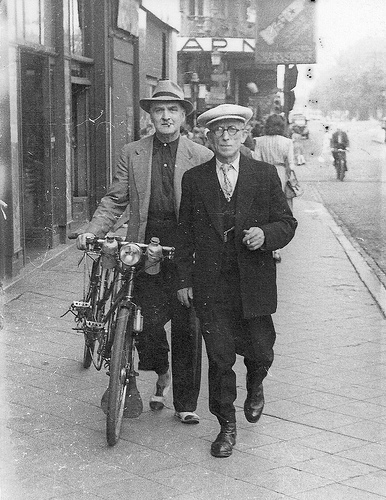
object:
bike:
[56, 225, 184, 448]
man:
[86, 108, 191, 433]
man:
[193, 119, 311, 463]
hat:
[137, 76, 195, 110]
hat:
[194, 103, 266, 131]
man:
[173, 102, 293, 452]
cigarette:
[244, 233, 258, 250]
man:
[176, 108, 333, 391]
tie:
[209, 148, 281, 205]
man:
[329, 125, 349, 174]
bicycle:
[331, 147, 349, 179]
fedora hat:
[135, 78, 201, 115]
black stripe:
[148, 89, 182, 98]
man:
[76, 65, 224, 427]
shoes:
[176, 409, 201, 424]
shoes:
[150, 374, 171, 410]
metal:
[146, 240, 164, 281]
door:
[15, 46, 53, 265]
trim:
[15, 42, 57, 264]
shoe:
[171, 402, 199, 425]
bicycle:
[69, 229, 185, 445]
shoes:
[143, 369, 166, 410]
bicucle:
[52, 222, 167, 437]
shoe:
[212, 422, 242, 457]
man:
[135, 78, 200, 165]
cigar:
[166, 121, 170, 131]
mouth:
[162, 120, 170, 129]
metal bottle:
[141, 236, 167, 277]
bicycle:
[58, 228, 178, 449]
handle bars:
[66, 227, 174, 274]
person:
[176, 90, 319, 472]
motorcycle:
[328, 148, 350, 184]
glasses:
[198, 120, 254, 143]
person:
[327, 123, 350, 186]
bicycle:
[329, 148, 350, 186]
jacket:
[79, 133, 218, 242]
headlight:
[119, 240, 141, 268]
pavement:
[294, 335, 380, 493]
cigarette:
[164, 121, 173, 125]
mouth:
[158, 120, 176, 128]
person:
[252, 108, 299, 217]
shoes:
[143, 373, 203, 432]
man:
[110, 72, 205, 442]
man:
[76, 80, 218, 427]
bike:
[71, 215, 173, 441]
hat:
[193, 103, 255, 127]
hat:
[136, 76, 186, 104]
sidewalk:
[261, 212, 377, 492]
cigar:
[166, 121, 175, 131]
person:
[330, 124, 348, 169]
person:
[72, 75, 215, 431]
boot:
[212, 413, 237, 458]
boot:
[246, 373, 266, 421]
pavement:
[25, 184, 373, 497]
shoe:
[173, 407, 201, 427]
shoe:
[151, 376, 171, 413]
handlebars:
[82, 234, 180, 279]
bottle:
[144, 237, 161, 278]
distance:
[0, 15, 374, 290]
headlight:
[119, 243, 145, 270]